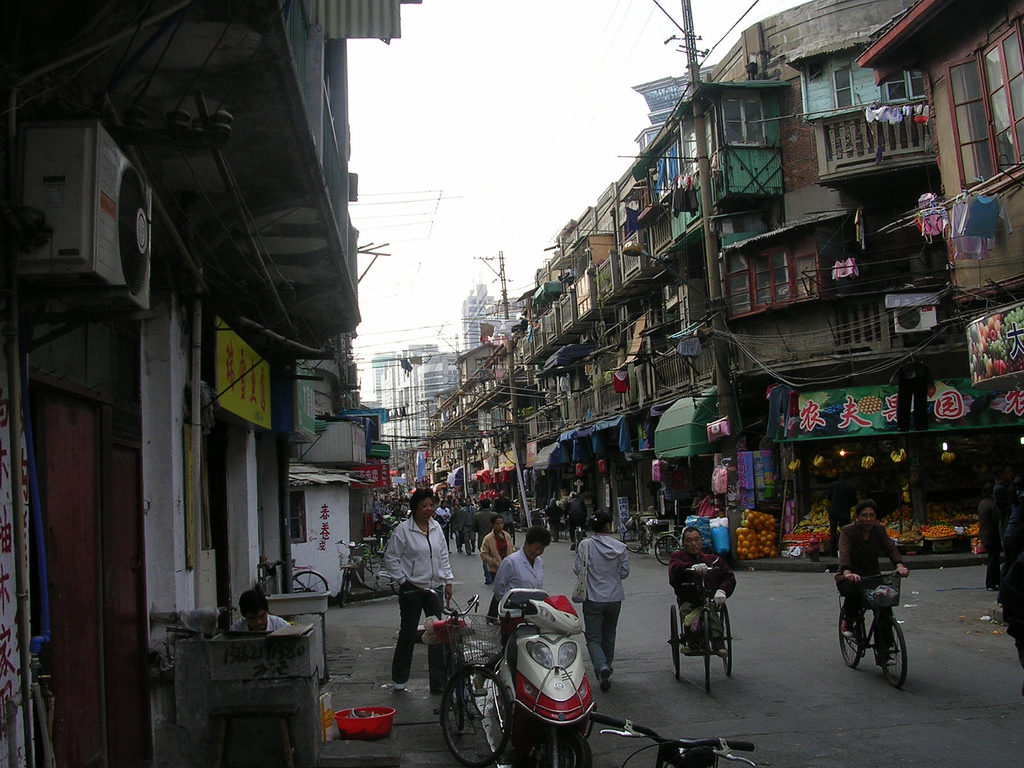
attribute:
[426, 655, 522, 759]
tire — black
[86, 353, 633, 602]
people — enjoying the outdoors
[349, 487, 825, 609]
people — walking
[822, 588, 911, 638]
tire — black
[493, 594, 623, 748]
bike — red and white